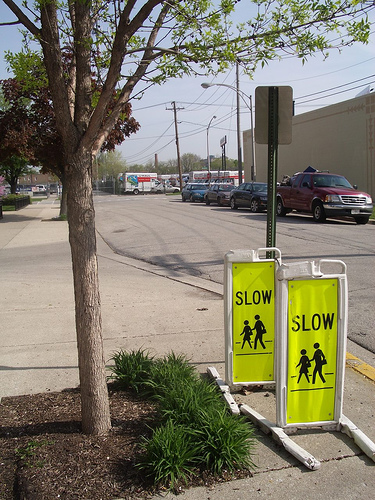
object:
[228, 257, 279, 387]
sign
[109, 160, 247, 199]
uhaul trucks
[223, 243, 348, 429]
sign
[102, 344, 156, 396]
bush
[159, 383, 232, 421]
bush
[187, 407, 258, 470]
bush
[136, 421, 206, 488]
bush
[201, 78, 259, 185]
light post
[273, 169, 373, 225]
cars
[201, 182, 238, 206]
cars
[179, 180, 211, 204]
cars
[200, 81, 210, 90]
light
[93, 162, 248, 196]
lot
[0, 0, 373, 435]
tree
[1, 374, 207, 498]
mulch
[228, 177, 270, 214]
car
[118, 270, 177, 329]
grey concrete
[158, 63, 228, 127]
sky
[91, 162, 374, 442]
street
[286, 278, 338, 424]
sign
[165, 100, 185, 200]
pole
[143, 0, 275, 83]
plants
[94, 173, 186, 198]
fence